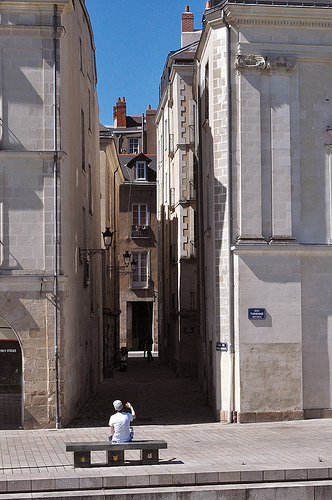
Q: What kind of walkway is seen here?
A: Smooth brick stone.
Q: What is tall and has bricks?
A: Building.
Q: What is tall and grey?
A: Brick walled building.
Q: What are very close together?
A: Buildings.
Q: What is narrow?
A: The alley.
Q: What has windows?
A: The house.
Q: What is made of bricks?
A: The wall.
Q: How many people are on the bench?
A: 1.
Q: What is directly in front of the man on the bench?
A: Alley.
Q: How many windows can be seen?
A: 4.